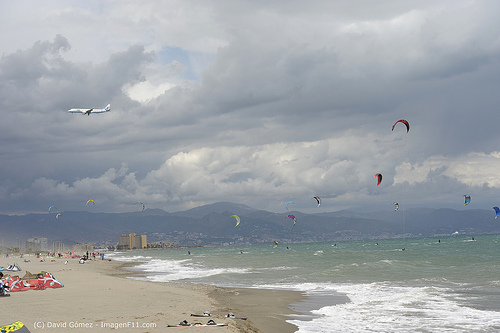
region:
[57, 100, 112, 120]
Plane flying in the air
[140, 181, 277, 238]
Mountain in the background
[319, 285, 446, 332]
White foam in the ocean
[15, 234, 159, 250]
Line of buildings on the coast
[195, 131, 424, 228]
Group of parasails over the water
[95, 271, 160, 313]
The sand on the beach is wet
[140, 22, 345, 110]
The sky is cloudy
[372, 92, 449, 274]
People skiing with the help of parachutes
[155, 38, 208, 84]
Blue sky showing through the clouds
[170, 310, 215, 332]
People's shoes on the beach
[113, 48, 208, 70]
this is the sky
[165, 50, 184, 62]
the sky is blue in color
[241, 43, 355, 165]
the sky is full of clouds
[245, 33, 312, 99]
the clouds are white in color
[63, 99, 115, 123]
this is an airplane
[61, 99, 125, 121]
the airplane is in the air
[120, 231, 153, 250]
this is a building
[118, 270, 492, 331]
this is a beach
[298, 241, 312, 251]
the water is blue in color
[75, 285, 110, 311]
the sand is brown in color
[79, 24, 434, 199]
this is the sky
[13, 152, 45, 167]
the sky is blue in color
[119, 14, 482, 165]
the sky is full of clouds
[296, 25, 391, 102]
the clouds are white in color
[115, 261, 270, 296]
this is the beach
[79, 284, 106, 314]
this is the sand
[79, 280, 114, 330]
the sand is brown in color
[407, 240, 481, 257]
the water is blue in color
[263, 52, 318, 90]
part of a cloud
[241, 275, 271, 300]
edge of a shore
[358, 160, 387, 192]
part of a parachute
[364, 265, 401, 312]
part of a shore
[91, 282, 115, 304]
part of a beach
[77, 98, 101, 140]
part of a plane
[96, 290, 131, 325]
part of some sand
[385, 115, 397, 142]
tip of a parachute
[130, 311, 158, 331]
part of a graphic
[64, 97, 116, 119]
an airplane flying over the beach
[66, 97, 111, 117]
the airplane is white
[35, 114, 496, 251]
many kites flying in the air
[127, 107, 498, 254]
some kites are flying over the water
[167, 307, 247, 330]
flip flops in the sand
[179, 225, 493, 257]
people out in the water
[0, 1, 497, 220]
the sky is very cloudy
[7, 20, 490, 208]
the clouds are white and gray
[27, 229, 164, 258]
hotels on the ocean front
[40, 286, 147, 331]
the sand is dry here.